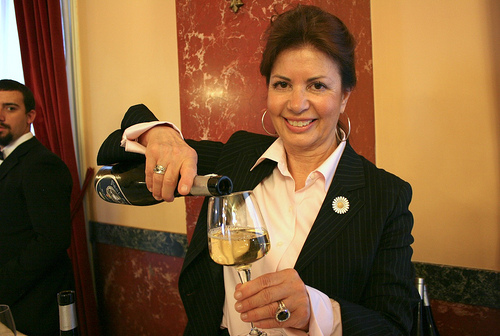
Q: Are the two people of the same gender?
A: No, they are both male and female.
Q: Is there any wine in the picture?
A: Yes, there is wine.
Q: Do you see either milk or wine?
A: Yes, there is wine.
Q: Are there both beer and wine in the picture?
A: No, there is wine but no beer.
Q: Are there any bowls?
A: No, there are no bowls.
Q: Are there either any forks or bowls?
A: No, there are no bowls or forks.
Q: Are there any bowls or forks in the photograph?
A: No, there are no bowls or forks.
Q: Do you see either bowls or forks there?
A: No, there are no bowls or forks.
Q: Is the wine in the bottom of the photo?
A: Yes, the wine is in the bottom of the image.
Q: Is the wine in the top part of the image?
A: No, the wine is in the bottom of the image.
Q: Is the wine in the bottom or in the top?
A: The wine is in the bottom of the image.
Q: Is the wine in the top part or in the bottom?
A: The wine is in the bottom of the image.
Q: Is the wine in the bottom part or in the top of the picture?
A: The wine is in the bottom of the image.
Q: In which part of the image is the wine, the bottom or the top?
A: The wine is in the bottom of the image.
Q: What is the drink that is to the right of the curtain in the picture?
A: The drink is wine.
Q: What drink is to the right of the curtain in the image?
A: The drink is wine.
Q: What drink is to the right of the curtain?
A: The drink is wine.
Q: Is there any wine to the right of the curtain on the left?
A: Yes, there is wine to the right of the curtain.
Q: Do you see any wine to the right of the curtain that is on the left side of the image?
A: Yes, there is wine to the right of the curtain.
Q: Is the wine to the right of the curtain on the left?
A: Yes, the wine is to the right of the curtain.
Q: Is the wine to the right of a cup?
A: No, the wine is to the right of the curtain.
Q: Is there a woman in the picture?
A: Yes, there is a woman.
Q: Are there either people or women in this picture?
A: Yes, there is a woman.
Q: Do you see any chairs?
A: No, there are no chairs.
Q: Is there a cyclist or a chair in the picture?
A: No, there are no chairs or cyclists.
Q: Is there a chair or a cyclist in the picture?
A: No, there are no chairs or cyclists.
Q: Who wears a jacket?
A: The woman wears a jacket.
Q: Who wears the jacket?
A: The woman wears a jacket.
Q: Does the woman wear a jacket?
A: Yes, the woman wears a jacket.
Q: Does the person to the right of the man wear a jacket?
A: Yes, the woman wears a jacket.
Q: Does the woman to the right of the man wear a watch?
A: No, the woman wears a jacket.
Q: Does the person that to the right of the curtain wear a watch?
A: No, the woman wears a jacket.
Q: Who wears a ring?
A: The woman wears a ring.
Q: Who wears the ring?
A: The woman wears a ring.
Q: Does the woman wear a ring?
A: Yes, the woman wears a ring.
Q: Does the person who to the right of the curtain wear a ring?
A: Yes, the woman wears a ring.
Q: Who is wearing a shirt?
A: The woman is wearing a shirt.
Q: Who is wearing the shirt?
A: The woman is wearing a shirt.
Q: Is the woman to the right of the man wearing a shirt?
A: Yes, the woman is wearing a shirt.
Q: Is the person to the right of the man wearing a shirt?
A: Yes, the woman is wearing a shirt.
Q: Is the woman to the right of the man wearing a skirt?
A: No, the woman is wearing a shirt.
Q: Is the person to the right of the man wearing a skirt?
A: No, the woman is wearing a shirt.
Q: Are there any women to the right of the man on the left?
A: Yes, there is a woman to the right of the man.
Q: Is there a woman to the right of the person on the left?
A: Yes, there is a woman to the right of the man.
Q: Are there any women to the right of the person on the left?
A: Yes, there is a woman to the right of the man.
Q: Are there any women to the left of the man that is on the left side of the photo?
A: No, the woman is to the right of the man.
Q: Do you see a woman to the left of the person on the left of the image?
A: No, the woman is to the right of the man.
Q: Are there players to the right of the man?
A: No, there is a woman to the right of the man.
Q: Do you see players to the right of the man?
A: No, there is a woman to the right of the man.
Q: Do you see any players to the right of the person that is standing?
A: No, there is a woman to the right of the man.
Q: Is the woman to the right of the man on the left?
A: Yes, the woman is to the right of the man.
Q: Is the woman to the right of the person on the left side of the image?
A: Yes, the woman is to the right of the man.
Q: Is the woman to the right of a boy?
A: No, the woman is to the right of the man.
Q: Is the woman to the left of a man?
A: No, the woman is to the right of a man.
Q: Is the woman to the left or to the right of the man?
A: The woman is to the right of the man.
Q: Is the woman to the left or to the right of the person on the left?
A: The woman is to the right of the man.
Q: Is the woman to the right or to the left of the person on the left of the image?
A: The woman is to the right of the man.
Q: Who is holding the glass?
A: The woman is holding the glass.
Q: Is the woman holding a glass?
A: Yes, the woman is holding a glass.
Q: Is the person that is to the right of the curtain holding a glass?
A: Yes, the woman is holding a glass.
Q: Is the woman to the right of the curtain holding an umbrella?
A: No, the woman is holding a glass.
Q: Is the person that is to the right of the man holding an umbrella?
A: No, the woman is holding a glass.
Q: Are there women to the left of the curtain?
A: No, the woman is to the right of the curtain.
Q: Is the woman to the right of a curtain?
A: Yes, the woman is to the right of a curtain.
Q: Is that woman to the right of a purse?
A: No, the woman is to the right of a curtain.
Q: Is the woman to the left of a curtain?
A: No, the woman is to the right of a curtain.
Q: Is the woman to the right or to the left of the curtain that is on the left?
A: The woman is to the right of the curtain.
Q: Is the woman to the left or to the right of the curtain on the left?
A: The woman is to the right of the curtain.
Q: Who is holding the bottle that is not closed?
A: The woman is holding the bottle.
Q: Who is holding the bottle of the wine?
A: The woman is holding the bottle.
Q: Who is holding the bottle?
A: The woman is holding the bottle.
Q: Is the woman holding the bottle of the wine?
A: Yes, the woman is holding the bottle.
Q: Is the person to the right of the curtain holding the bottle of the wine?
A: Yes, the woman is holding the bottle.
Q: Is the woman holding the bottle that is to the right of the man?
A: Yes, the woman is holding the bottle.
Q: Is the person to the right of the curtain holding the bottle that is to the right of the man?
A: Yes, the woman is holding the bottle.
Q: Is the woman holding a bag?
A: No, the woman is holding the bottle.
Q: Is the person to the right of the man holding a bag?
A: No, the woman is holding the bottle.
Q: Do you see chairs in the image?
A: No, there are no chairs.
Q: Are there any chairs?
A: No, there are no chairs.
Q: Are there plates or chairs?
A: No, there are no chairs or plates.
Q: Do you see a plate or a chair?
A: No, there are no chairs or plates.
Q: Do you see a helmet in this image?
A: No, there are no helmets.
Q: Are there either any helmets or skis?
A: No, there are no helmets or skis.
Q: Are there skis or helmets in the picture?
A: No, there are no helmets or skis.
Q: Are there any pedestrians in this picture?
A: No, there are no pedestrians.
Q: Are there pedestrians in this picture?
A: No, there are no pedestrians.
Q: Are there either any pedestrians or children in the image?
A: No, there are no pedestrians or children.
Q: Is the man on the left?
A: Yes, the man is on the left of the image.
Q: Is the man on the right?
A: No, the man is on the left of the image.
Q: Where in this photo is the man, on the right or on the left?
A: The man is on the left of the image.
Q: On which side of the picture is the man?
A: The man is on the left of the image.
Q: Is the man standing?
A: Yes, the man is standing.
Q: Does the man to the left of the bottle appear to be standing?
A: Yes, the man is standing.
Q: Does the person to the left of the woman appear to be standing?
A: Yes, the man is standing.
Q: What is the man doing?
A: The man is standing.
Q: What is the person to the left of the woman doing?
A: The man is standing.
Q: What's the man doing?
A: The man is standing.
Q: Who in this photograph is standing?
A: The man is standing.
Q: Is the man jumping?
A: No, the man is standing.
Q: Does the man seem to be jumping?
A: No, the man is standing.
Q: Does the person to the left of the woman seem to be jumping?
A: No, the man is standing.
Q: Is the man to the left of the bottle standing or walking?
A: The man is standing.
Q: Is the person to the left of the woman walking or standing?
A: The man is standing.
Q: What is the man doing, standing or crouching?
A: The man is standing.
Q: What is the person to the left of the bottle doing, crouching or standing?
A: The man is standing.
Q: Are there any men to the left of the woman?
A: Yes, there is a man to the left of the woman.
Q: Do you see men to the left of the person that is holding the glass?
A: Yes, there is a man to the left of the woman.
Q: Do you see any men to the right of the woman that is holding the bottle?
A: No, the man is to the left of the woman.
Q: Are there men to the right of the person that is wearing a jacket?
A: No, the man is to the left of the woman.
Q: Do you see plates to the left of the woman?
A: No, there is a man to the left of the woman.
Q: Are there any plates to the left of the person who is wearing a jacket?
A: No, there is a man to the left of the woman.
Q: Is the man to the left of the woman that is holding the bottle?
A: Yes, the man is to the left of the woman.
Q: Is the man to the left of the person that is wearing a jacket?
A: Yes, the man is to the left of the woman.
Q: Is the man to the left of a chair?
A: No, the man is to the left of the woman.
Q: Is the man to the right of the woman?
A: No, the man is to the left of the woman.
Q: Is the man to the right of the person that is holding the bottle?
A: No, the man is to the left of the woman.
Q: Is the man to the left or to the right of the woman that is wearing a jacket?
A: The man is to the left of the woman.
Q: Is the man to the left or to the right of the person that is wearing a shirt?
A: The man is to the left of the woman.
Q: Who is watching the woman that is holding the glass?
A: The man is watching the woman.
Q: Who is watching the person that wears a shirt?
A: The man is watching the woman.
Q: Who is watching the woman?
A: The man is watching the woman.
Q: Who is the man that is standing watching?
A: The man is watching the woman.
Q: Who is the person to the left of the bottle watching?
A: The man is watching the woman.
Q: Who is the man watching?
A: The man is watching the woman.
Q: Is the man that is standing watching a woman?
A: Yes, the man is watching a woman.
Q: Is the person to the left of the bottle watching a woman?
A: Yes, the man is watching a woman.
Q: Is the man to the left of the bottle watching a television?
A: No, the man is watching a woman.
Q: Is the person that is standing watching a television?
A: No, the man is watching a woman.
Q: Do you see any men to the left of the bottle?
A: Yes, there is a man to the left of the bottle.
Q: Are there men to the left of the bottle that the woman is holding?
A: Yes, there is a man to the left of the bottle.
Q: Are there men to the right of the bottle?
A: No, the man is to the left of the bottle.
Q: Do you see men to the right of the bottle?
A: No, the man is to the left of the bottle.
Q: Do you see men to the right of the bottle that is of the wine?
A: No, the man is to the left of the bottle.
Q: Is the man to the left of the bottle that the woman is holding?
A: Yes, the man is to the left of the bottle.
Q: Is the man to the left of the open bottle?
A: Yes, the man is to the left of the bottle.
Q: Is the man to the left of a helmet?
A: No, the man is to the left of the bottle.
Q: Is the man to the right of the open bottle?
A: No, the man is to the left of the bottle.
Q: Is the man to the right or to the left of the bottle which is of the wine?
A: The man is to the left of the bottle.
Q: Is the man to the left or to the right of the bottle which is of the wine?
A: The man is to the left of the bottle.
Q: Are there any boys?
A: No, there are no boys.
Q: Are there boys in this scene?
A: No, there are no boys.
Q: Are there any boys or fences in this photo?
A: No, there are no boys or fences.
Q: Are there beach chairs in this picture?
A: No, there are no beach chairs.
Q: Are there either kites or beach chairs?
A: No, there are no beach chairs or kites.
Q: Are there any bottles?
A: Yes, there is a bottle.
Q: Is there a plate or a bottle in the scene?
A: Yes, there is a bottle.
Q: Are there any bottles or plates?
A: Yes, there is a bottle.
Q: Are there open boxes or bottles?
A: Yes, there is an open bottle.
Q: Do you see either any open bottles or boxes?
A: Yes, there is an open bottle.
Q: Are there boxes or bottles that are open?
A: Yes, the bottle is open.